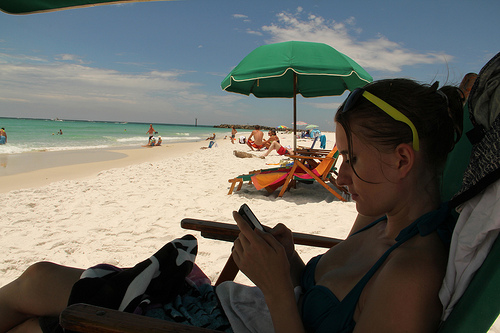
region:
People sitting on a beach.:
[0, 1, 496, 331]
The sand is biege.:
[58, 172, 213, 208]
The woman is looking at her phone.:
[222, 80, 462, 330]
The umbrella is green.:
[220, 33, 367, 203]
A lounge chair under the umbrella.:
[241, 127, 337, 205]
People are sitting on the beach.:
[222, 115, 294, 160]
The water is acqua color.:
[8, 122, 48, 139]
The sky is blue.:
[15, 11, 186, 46]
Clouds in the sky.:
[0, 0, 495, 105]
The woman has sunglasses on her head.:
[331, 80, 424, 167]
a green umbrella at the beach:
[216, 57, 263, 109]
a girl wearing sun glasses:
[351, 86, 393, 126]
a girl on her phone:
[219, 199, 285, 245]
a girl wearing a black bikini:
[308, 277, 362, 326]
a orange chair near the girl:
[224, 174, 275, 196]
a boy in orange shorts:
[246, 135, 269, 155]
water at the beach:
[53, 126, 118, 154]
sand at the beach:
[57, 175, 109, 201]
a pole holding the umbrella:
[281, 92, 323, 120]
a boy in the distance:
[132, 116, 179, 148]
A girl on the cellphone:
[221, 192, 289, 261]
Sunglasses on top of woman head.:
[327, 78, 428, 133]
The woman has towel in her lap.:
[87, 233, 209, 310]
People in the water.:
[2, 120, 89, 141]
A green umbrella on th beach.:
[225, 72, 384, 100]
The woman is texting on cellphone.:
[168, 180, 365, 282]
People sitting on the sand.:
[228, 127, 295, 156]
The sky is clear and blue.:
[38, 18, 170, 130]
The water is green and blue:
[14, 110, 114, 140]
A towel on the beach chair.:
[228, 153, 325, 196]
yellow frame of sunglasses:
[343, 81, 438, 160]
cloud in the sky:
[259, 3, 455, 93]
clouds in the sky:
[16, 48, 197, 114]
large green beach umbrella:
[211, 22, 376, 199]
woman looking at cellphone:
[173, 71, 459, 331]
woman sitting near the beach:
[2, 49, 494, 331]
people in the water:
[117, 105, 171, 154]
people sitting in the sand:
[231, 120, 288, 160]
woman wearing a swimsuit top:
[285, 182, 420, 327]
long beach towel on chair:
[226, 137, 340, 210]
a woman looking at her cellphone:
[208, 73, 448, 319]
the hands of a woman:
[221, 206, 299, 293]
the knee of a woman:
[12, 253, 60, 282]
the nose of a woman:
[333, 163, 356, 188]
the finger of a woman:
[228, 209, 265, 239]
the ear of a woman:
[393, 143, 414, 177]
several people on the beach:
[48, 116, 285, 163]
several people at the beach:
[2, 101, 298, 193]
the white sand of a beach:
[15, 152, 160, 243]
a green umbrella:
[216, 38, 373, 98]